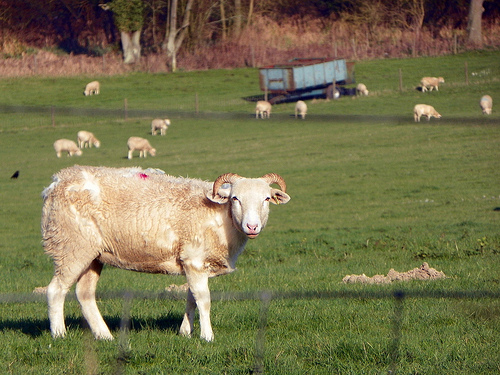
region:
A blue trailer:
[255, 55, 351, 101]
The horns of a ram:
[212, 157, 287, 199]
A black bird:
[8, 169, 21, 180]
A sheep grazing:
[411, 102, 441, 126]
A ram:
[41, 164, 289, 343]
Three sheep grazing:
[52, 126, 154, 162]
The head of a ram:
[204, 169, 292, 239]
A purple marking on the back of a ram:
[137, 170, 151, 180]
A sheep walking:
[418, 69, 445, 94]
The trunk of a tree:
[462, 0, 487, 52]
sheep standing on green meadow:
[22, 27, 484, 348]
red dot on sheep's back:
[37, 145, 297, 251]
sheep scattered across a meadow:
[25, 51, 490, 156]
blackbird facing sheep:
[5, 120, 85, 190]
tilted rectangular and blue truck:
[236, 46, 373, 118]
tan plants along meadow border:
[25, 10, 460, 80]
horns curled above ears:
[190, 156, 302, 242]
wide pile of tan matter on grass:
[311, 251, 466, 301]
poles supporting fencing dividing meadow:
[30, 25, 445, 136]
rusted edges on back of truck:
[245, 46, 315, 101]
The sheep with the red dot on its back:
[35, 155, 289, 347]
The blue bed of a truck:
[258, 59, 366, 101]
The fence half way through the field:
[0, 58, 499, 124]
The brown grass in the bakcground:
[0, 19, 497, 78]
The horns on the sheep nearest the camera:
[210, 169, 287, 199]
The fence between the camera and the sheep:
[2, 100, 499, 372]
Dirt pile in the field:
[337, 259, 453, 288]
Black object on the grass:
[6, 165, 23, 183]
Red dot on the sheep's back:
[135, 168, 150, 184]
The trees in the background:
[104, 0, 489, 70]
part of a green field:
[332, 145, 445, 235]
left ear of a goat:
[267, 190, 292, 207]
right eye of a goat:
[228, 192, 240, 204]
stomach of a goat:
[107, 217, 159, 276]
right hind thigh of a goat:
[49, 250, 88, 282]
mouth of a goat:
[243, 230, 261, 245]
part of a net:
[243, 282, 391, 354]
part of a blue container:
[289, 64, 329, 86]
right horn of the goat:
[208, 168, 233, 194]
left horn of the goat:
[261, 170, 289, 188]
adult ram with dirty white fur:
[28, 157, 304, 351]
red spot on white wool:
[131, 160, 161, 187]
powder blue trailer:
[251, 54, 368, 104]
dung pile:
[342, 253, 454, 298]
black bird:
[8, 161, 28, 185]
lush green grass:
[272, 298, 499, 373]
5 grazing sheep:
[45, 74, 188, 166]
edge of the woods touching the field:
[3, 1, 495, 84]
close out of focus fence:
[1, 280, 498, 366]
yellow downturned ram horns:
[207, 160, 295, 204]